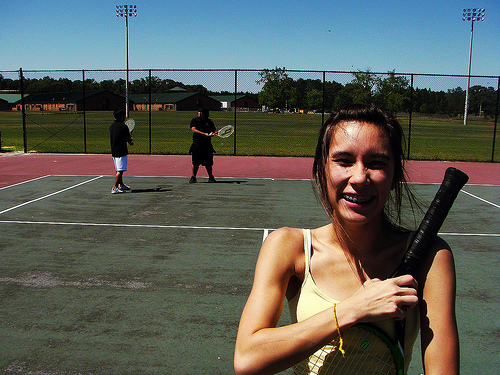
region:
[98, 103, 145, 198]
person is playing tennis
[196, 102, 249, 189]
person is playing tennis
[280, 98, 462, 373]
person is playing tennis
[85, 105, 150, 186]
person is holding a tennis racket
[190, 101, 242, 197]
person is holding a tennis racket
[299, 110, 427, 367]
person is holding a tennis racket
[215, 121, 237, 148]
back wards P on tennis racket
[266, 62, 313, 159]
tall black chain linked fence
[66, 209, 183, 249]
white lines painted on ground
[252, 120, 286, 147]
short green grass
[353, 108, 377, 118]
woman has black hair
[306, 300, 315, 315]
woman wearing tan shirt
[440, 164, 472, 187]
bottom of black handle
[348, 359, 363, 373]
inside of tennis racket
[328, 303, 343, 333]
yellow bracelet on wrist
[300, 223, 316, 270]
tan strap on shoulder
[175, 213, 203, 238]
white line on court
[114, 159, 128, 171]
man wearing white shorts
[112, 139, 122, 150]
man wearing black shirt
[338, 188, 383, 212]
smile on womans face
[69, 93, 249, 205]
two people holding tennis rackets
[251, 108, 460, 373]
a woman holding a tennis racket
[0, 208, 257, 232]
white lines on a tennis court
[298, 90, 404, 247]
a girl with brown hair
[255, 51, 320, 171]
a black chain link fence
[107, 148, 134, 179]
a boy wearing white shorts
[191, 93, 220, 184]
a person wearing black clothing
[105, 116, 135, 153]
a person wearing a black shirt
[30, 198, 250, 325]
a green tennis court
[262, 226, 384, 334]
a woman wearing a sleeveless shirt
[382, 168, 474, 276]
black handle of tennis racket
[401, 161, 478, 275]
black handle of racket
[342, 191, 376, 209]
white teeth of girl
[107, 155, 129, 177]
white shorts on man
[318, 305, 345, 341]
yellow bracelet on girls arm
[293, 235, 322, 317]
yellow tank top on girl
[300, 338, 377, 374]
white wires of racket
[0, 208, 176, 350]
green tennis court top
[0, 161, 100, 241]
white lines on tennis court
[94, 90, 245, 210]
two guys holding rackets